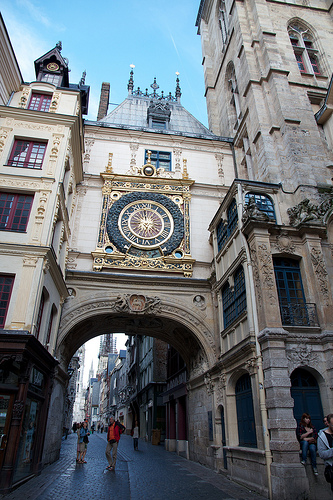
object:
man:
[105, 414, 121, 472]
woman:
[76, 422, 83, 462]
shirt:
[106, 420, 125, 443]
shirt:
[79, 427, 91, 445]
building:
[0, 0, 333, 500]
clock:
[91, 172, 197, 278]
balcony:
[207, 177, 283, 254]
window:
[287, 23, 322, 74]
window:
[224, 61, 242, 136]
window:
[7, 133, 49, 170]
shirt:
[317, 427, 333, 470]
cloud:
[0, 0, 208, 130]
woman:
[299, 412, 319, 477]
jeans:
[300, 440, 317, 469]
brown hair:
[299, 413, 313, 427]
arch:
[55, 291, 220, 372]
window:
[0, 190, 36, 232]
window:
[235, 373, 258, 449]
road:
[0, 431, 267, 500]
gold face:
[106, 190, 185, 258]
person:
[130, 420, 140, 452]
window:
[290, 367, 327, 435]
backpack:
[114, 419, 126, 434]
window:
[27, 89, 54, 112]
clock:
[46, 62, 60, 72]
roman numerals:
[122, 203, 171, 247]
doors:
[163, 394, 187, 457]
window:
[221, 264, 247, 330]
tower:
[33, 40, 71, 89]